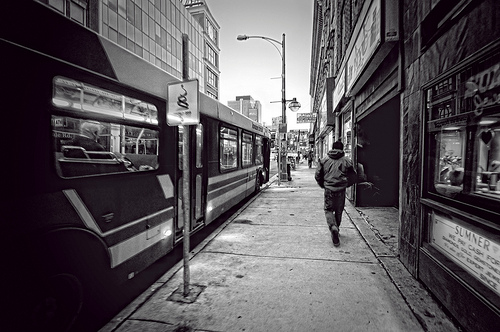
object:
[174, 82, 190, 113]
sign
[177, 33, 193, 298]
pole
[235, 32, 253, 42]
light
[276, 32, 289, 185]
pole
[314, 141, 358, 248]
person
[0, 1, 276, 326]
bus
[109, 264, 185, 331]
curb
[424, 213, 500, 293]
sign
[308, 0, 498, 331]
building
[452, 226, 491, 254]
sumner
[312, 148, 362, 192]
jacket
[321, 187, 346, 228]
pants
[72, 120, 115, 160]
person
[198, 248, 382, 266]
lines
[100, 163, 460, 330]
sidewalk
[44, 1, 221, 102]
building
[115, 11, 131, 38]
panels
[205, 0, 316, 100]
sky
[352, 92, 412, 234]
entryway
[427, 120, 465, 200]
windows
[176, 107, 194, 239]
door